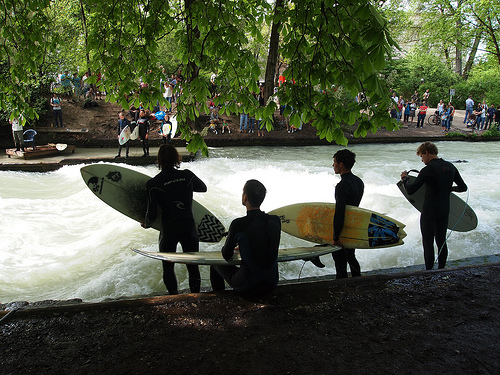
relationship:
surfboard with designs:
[78, 162, 228, 244] [87, 167, 120, 194]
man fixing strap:
[415, 141, 467, 271] [405, 167, 473, 261]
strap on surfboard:
[405, 167, 473, 261] [395, 172, 479, 234]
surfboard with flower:
[265, 202, 407, 250] [369, 219, 401, 245]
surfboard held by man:
[255, 178, 414, 268] [140, 143, 208, 295]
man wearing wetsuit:
[140, 143, 208, 295] [146, 170, 204, 290]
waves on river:
[1, 141, 498, 301] [10, 140, 483, 310]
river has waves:
[3, 132, 498, 304] [41, 157, 381, 297]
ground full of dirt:
[3, 244, 499, 372] [3, 317, 498, 370]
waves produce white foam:
[1, 161, 157, 292] [53, 242, 129, 288]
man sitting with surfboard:
[204, 171, 290, 303] [126, 239, 351, 261]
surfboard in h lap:
[126, 239, 351, 261] [209, 260, 270, 294]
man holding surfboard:
[143, 141, 208, 299] [78, 162, 228, 244]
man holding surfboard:
[328, 148, 368, 282] [264, 199, 406, 249]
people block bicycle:
[416, 100, 456, 128] [428, 112, 446, 126]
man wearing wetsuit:
[400, 141, 467, 271] [402, 158, 465, 278]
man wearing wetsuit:
[140, 143, 208, 295] [212, 210, 284, 308]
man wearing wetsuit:
[209, 179, 282, 303] [137, 166, 208, 290]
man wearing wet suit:
[209, 179, 282, 303] [207, 209, 283, 294]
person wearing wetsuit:
[134, 108, 152, 158] [135, 117, 151, 153]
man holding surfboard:
[400, 141, 467, 271] [395, 172, 479, 234]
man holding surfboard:
[400, 141, 467, 271] [260, 200, 407, 253]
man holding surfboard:
[331, 148, 364, 279] [133, 238, 341, 266]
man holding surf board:
[143, 141, 208, 299] [78, 154, 226, 246]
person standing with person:
[461, 93, 479, 125] [433, 98, 444, 117]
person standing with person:
[433, 98, 444, 117] [414, 100, 427, 127]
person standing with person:
[423, 87, 432, 104] [410, 87, 421, 103]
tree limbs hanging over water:
[146, 42, 358, 156] [30, 179, 107, 246]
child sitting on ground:
[210, 109, 219, 131] [2, 88, 484, 158]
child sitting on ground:
[217, 107, 234, 131] [2, 88, 484, 158]